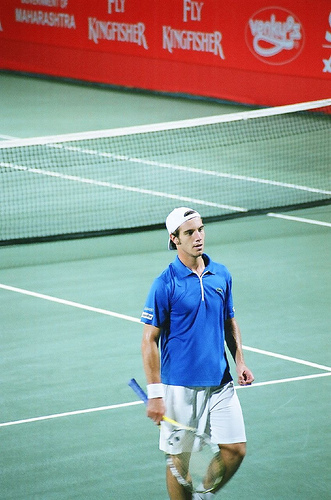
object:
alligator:
[214, 284, 226, 298]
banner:
[2, 0, 330, 118]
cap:
[164, 203, 201, 250]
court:
[1, 69, 328, 498]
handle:
[126, 375, 180, 434]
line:
[2, 276, 331, 380]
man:
[141, 204, 252, 500]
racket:
[128, 373, 229, 494]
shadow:
[2, 224, 330, 271]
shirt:
[142, 252, 237, 389]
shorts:
[157, 379, 247, 457]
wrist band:
[146, 380, 167, 397]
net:
[1, 91, 328, 254]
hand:
[144, 398, 166, 419]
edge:
[164, 455, 191, 490]